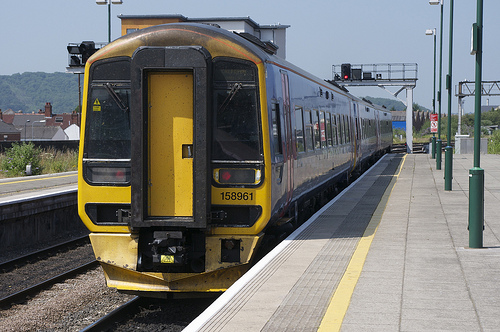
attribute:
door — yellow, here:
[145, 69, 196, 216]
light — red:
[117, 163, 131, 187]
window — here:
[86, 67, 129, 162]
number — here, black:
[218, 188, 259, 205]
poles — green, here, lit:
[413, 0, 490, 250]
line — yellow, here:
[300, 141, 408, 331]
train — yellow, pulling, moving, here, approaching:
[64, 25, 393, 316]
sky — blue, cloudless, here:
[2, 2, 498, 110]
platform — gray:
[194, 150, 498, 327]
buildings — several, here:
[0, 103, 80, 152]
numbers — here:
[218, 188, 255, 204]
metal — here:
[112, 208, 130, 224]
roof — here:
[131, 21, 246, 52]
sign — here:
[428, 111, 444, 140]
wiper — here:
[103, 82, 129, 110]